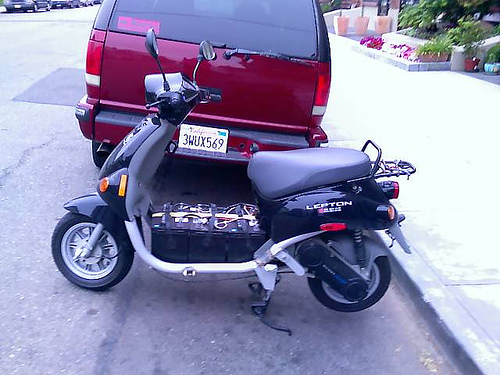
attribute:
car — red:
[117, 1, 382, 152]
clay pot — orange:
[330, 15, 351, 36]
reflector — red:
[311, 218, 357, 236]